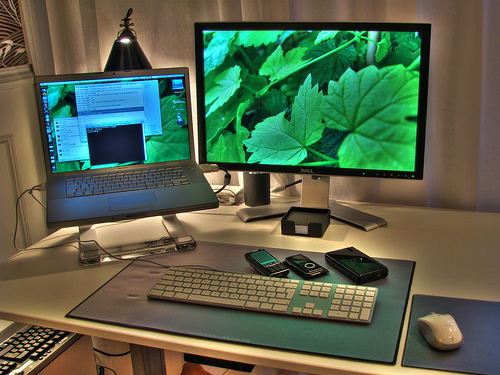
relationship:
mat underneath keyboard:
[62, 235, 419, 371] [148, 266, 379, 324]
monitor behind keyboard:
[194, 22, 433, 209] [150, 266, 381, 326]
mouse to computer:
[415, 312, 461, 353] [37, 16, 465, 350]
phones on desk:
[240, 228, 415, 308] [25, 119, 498, 371]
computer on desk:
[32, 66, 226, 229] [1, 183, 498, 374]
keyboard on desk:
[148, 266, 379, 324] [0, 152, 496, 370]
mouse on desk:
[415, 309, 465, 352] [0, 152, 496, 370]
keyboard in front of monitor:
[148, 266, 379, 324] [196, 21, 441, 181]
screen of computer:
[35, 74, 192, 176] [32, 66, 226, 229]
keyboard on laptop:
[56, 161, 196, 200] [18, 65, 224, 229]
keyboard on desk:
[134, 251, 385, 344] [0, 152, 496, 370]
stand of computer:
[279, 158, 352, 228] [144, 0, 446, 232]